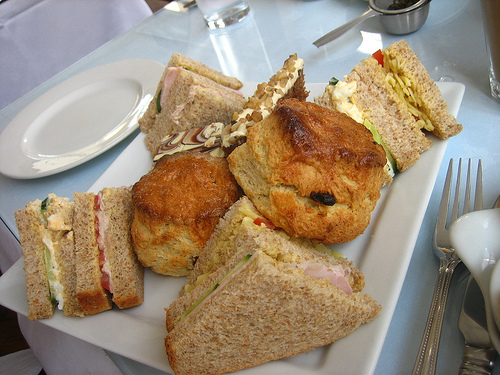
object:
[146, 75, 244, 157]
sandwich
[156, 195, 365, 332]
sandwich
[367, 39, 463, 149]
sandwich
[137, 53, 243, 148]
sandwich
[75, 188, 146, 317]
sandwich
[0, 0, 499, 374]
table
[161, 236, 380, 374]
sandwich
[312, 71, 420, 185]
sandwich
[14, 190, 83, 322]
sandwich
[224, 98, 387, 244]
biscuit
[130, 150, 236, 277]
biscuit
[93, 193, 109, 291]
meat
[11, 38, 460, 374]
food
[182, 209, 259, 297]
pastry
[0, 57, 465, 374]
plate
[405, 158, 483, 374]
fork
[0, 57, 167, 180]
plate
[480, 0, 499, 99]
glass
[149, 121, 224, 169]
dessert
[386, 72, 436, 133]
pastry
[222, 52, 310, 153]
cake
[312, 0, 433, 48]
container